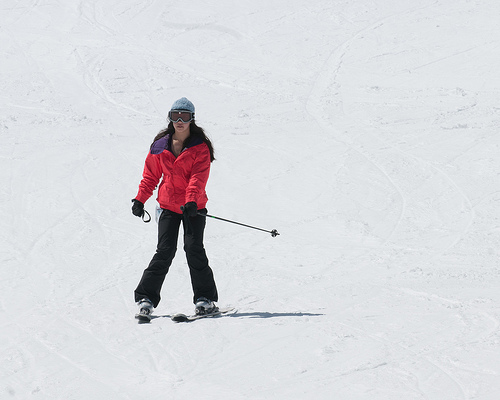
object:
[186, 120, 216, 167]
long hair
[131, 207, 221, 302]
black pants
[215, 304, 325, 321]
shadow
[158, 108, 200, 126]
goggles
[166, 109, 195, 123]
eyes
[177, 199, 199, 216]
hand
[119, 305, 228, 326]
skis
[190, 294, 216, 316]
foot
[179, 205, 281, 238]
pole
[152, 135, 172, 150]
purple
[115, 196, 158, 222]
glove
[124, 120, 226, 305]
color black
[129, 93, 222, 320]
female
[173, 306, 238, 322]
skis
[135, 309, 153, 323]
skis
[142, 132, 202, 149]
hood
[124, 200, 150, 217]
hand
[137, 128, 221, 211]
coat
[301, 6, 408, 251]
mark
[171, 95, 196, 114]
beanie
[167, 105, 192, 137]
face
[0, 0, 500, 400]
snow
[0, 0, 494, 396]
slope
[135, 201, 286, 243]
poles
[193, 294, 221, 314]
ski shoe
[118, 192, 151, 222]
ski pole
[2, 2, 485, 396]
ground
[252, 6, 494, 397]
track marks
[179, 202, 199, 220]
glove